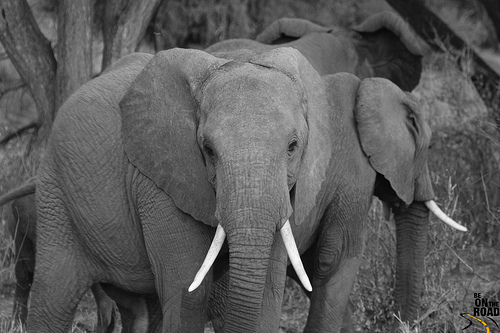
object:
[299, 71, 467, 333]
elephant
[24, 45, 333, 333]
elephant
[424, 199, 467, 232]
tusk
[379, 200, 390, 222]
tusk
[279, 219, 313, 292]
tusk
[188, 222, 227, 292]
tusk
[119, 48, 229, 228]
ear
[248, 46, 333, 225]
ear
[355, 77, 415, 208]
ear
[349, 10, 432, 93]
ear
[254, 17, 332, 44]
ear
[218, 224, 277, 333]
trunk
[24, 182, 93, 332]
leg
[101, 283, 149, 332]
leg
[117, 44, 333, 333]
herd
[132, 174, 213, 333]
leg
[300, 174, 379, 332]
leg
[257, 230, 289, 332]
leg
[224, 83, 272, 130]
wall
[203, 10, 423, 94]
elephant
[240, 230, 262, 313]
ridges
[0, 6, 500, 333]
grass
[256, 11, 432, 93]
head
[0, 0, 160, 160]
tree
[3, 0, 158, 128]
trunks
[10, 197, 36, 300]
stones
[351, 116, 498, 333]
bush